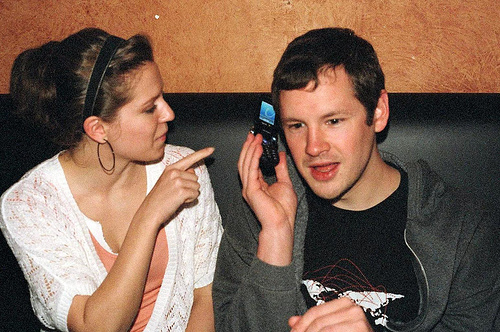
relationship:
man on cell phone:
[206, 16, 491, 330] [255, 85, 284, 185]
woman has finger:
[2, 26, 222, 327] [181, 143, 217, 164]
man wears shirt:
[206, 16, 491, 330] [286, 184, 422, 325]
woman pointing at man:
[2, 26, 222, 327] [210, 16, 500, 331]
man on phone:
[210, 16, 500, 331] [254, 94, 281, 175]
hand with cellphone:
[241, 130, 311, 234] [251, 98, 281, 176]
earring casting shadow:
[96, 138, 116, 171] [102, 170, 115, 175]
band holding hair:
[81, 31, 123, 122] [7, 26, 155, 169]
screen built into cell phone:
[259, 101, 277, 125] [247, 90, 281, 166]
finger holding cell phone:
[245, 141, 263, 191] [248, 96, 280, 167]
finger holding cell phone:
[241, 130, 263, 189] [248, 96, 280, 167]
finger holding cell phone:
[235, 130, 254, 184] [248, 96, 280, 167]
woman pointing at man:
[2, 26, 222, 327] [206, 16, 491, 330]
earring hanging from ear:
[93, 139, 114, 175] [82, 115, 107, 144]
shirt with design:
[301, 159, 421, 329] [299, 257, 409, 329]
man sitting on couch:
[206, 16, 491, 330] [1, 88, 499, 329]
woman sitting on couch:
[2, 26, 222, 327] [1, 88, 499, 329]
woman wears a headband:
[2, 26, 222, 327] [71, 26, 125, 131]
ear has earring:
[79, 114, 111, 146] [96, 138, 116, 171]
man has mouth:
[206, 16, 491, 330] [304, 157, 340, 184]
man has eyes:
[206, 16, 491, 330] [284, 115, 345, 127]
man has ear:
[206, 16, 491, 330] [372, 88, 393, 137]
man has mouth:
[206, 16, 491, 330] [306, 159, 340, 179]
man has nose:
[206, 16, 491, 330] [304, 121, 327, 155]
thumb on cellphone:
[272, 146, 292, 180] [228, 132, 302, 235]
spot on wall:
[152, 10, 166, 22] [139, 1, 246, 64]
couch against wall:
[1, 88, 499, 329] [4, 6, 498, 91]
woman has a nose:
[0, 26, 226, 332] [158, 100, 172, 122]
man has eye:
[206, 16, 491, 330] [321, 109, 351, 129]